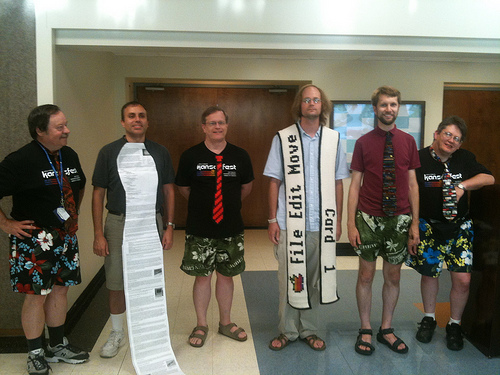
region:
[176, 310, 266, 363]
a man in a pair of sandals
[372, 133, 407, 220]
a man wearing a tie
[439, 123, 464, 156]
a person wearing glasses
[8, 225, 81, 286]
a pair of floral pattern shorts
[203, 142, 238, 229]
a man wearing a red striped tie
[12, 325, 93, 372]
a man wearing a pair of sneakers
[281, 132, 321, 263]
a man wearing a scarf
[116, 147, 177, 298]
a man with paper on his shirt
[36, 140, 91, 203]
a man wearing a blue necklace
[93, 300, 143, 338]
a man wearing white socks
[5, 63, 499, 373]
A group of men standing in a room.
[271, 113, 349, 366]
Man is wearing a white and black stole around his neck.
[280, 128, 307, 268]
The black text on the stole says file edit move.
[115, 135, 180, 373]
The man is wearing a long paper tie.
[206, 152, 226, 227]
The man is wearing a red and black tie.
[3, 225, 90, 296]
The man is wearing floral shorts.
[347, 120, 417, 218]
The man is wearing a red t-shirt.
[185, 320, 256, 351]
The man is wearing sandals.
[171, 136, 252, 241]
The man is wearing a black t-shirt.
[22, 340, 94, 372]
The man is wearing tennis shoes.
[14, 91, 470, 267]
Group of men standing together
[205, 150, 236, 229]
Man wearing a red and black tie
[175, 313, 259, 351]
Man is wearing sandals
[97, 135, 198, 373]
Man is wearing a long tie made of paper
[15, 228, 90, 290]
Man wearing bathing suit bottoms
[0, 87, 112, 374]
Man standing with hands on his hips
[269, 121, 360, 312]
Man wearing a long tie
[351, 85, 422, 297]
Man wearing mismatched clothing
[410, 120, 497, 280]
Man wearing a mismatched shirt and bathing suit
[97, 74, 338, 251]
Large door in background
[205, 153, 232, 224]
Red and black striped tie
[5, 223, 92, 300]
Flower Hawaiian shorts man is wearing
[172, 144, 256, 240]
Black shirt man is wearing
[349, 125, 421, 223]
Maroon shirt man is wearing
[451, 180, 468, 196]
Watch on person's wrist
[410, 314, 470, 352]
Black shoes on person's feet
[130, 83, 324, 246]
Brown wooden door to room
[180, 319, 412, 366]
Sandals men are wearing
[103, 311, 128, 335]
White sock man is wearing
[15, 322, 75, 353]
Black socks man is wearing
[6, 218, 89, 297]
colorful floral shorts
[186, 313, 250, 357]
grey shoes worn by a man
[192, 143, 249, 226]
a tie symbol on a t-shirt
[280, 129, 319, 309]
something worn that says File Edit Move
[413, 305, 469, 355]
someone wearing black tennis shoes and white socks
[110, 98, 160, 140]
the face of a smiling man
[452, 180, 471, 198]
a wristwatch worn on an arm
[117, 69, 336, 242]
some wooden doors to a meeting room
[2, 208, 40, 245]
the hand of a man on his hip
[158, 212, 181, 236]
a wristwatch on the left arm of a man